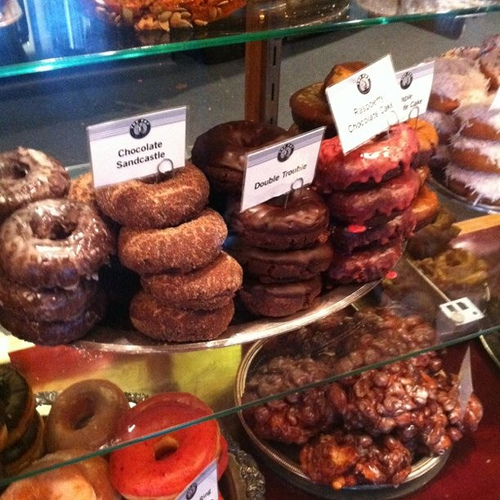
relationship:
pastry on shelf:
[90, 153, 215, 228] [0, 122, 496, 487]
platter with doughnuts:
[0, 390, 268, 499] [111, 399, 221, 498]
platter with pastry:
[0, 390, 268, 499] [116, 390, 228, 480]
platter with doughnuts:
[0, 390, 268, 499] [45, 378, 129, 451]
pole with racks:
[242, 30, 296, 144] [13, 15, 499, 92]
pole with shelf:
[242, 30, 296, 144] [4, 219, 486, 401]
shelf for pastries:
[4, 219, 486, 401] [2, 145, 450, 330]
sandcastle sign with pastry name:
[88, 102, 189, 189] [107, 140, 168, 170]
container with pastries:
[118, 243, 448, 491] [313, 355, 430, 437]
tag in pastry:
[243, 127, 338, 204] [244, 306, 455, 487]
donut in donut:
[276, 313, 344, 369] [298, 421, 415, 491]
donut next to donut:
[0, 199, 115, 289] [1, 279, 107, 328]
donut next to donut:
[1, 281, 108, 345] [3, 201, 109, 288]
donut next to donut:
[64, 167, 113, 221] [0, 199, 115, 289]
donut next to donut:
[91, 160, 213, 229] [115, 205, 229, 277]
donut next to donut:
[235, 243, 335, 283] [233, 189, 330, 251]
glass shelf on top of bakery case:
[1, 0, 498, 76] [2, 2, 494, 498]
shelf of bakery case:
[4, 219, 486, 401] [2, 2, 494, 498]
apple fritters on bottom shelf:
[252, 329, 470, 485] [97, 341, 489, 485]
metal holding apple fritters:
[221, 339, 496, 494] [244, 311, 473, 480]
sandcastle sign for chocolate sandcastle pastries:
[88, 102, 189, 189] [0, 133, 213, 364]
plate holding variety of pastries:
[75, 309, 412, 351] [94, 155, 210, 224]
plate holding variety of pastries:
[75, 309, 412, 351] [290, 80, 336, 135]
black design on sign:
[129, 117, 151, 139] [48, 69, 464, 303]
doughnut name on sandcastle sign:
[0, 160, 494, 433] [88, 102, 189, 189]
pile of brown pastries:
[82, 185, 465, 422] [101, 168, 211, 223]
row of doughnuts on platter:
[7, 395, 403, 498] [40, 222, 411, 354]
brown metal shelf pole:
[216, 52, 284, 168] [242, 3, 287, 145]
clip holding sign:
[141, 152, 176, 182] [116, 132, 161, 192]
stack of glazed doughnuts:
[75, 98, 454, 365] [97, 163, 212, 230]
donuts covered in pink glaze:
[313, 119, 404, 299] [341, 131, 415, 179]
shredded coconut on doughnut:
[449, 56, 496, 184] [10, 38, 495, 495]